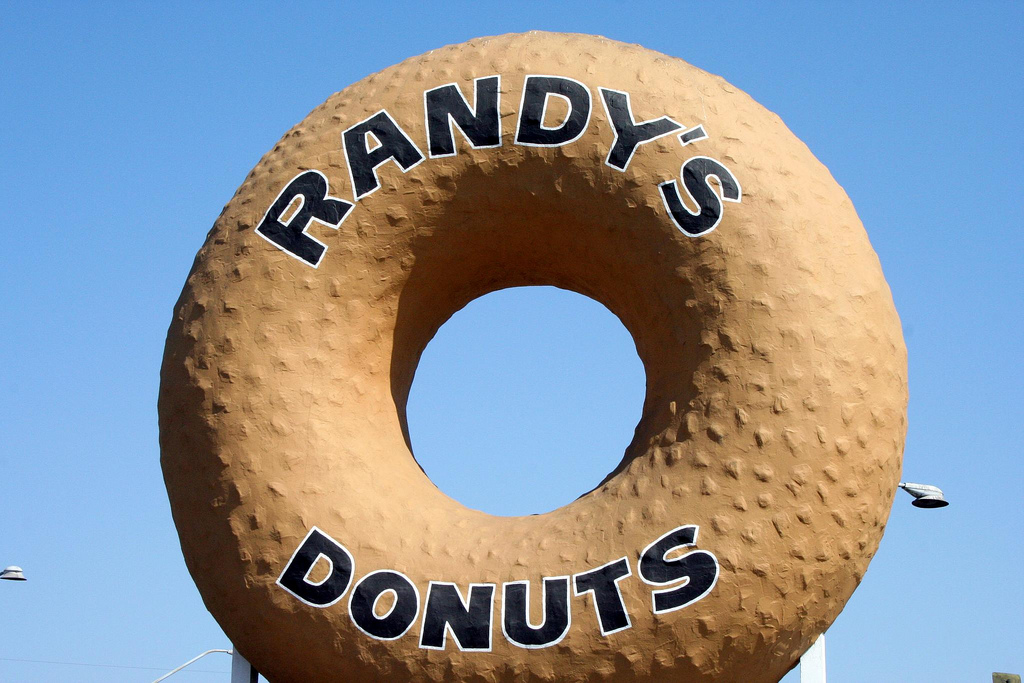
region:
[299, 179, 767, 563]
Blue sky can be seen through the center of the sign.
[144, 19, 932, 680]
a large brown doughnut-shaped sign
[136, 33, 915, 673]
large donunt shaped Randy Donunts sign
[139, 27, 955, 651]
Giant doughnut shop sign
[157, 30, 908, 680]
really large donut shaped sign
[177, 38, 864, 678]
The sign says Randy's Donuts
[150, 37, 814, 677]
There is a donut shaped sign for randy's donuts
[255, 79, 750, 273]
black and white lettering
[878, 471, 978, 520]
white protruding light to light up the donut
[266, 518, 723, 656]
black and white lettering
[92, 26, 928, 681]
giant brown sign with black and white letters advertising donuts for sale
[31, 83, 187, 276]
clear blue sky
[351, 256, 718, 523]
giant doughnut hole in "donut" sign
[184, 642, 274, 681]
pole holding up large donut sign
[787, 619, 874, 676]
support that is part of the structure holding up a sign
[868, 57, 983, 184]
cloudless sky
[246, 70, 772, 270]
large letter showing that something belongs to Randy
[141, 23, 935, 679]
a giant donut that says Randy's Donuts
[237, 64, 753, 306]
big words that say Randy's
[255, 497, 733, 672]
big words that say Donuts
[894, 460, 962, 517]
the light part of a light pole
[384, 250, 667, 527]
the donut hole of a giant donut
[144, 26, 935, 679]
a giant, bumpy textured donut statue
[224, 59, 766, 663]
giant words that say Randy's Donuts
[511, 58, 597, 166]
a giant letter D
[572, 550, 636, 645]
a giant letter T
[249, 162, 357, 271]
a giant letter R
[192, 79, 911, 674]
Round architectural object, meant to look like doughnut.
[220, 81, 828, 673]
Features black lettering, reading, "Randy's Donuts."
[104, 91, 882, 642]
Doughnut-shaped architecture shows pebbly texture and brown coloration.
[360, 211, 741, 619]
Doughnut hole is shadowed and shows sky behind it.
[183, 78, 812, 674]
Black letters are outlined in white.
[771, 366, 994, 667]
Doughnut-shaped item is high enough that street lamp appears to jut from side.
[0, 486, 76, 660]
Top of second light, of to side, on left.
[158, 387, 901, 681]
Doughnut architecture appears to be supported by white posts, positioned behind.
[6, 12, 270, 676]
Sky seems brightest at top and lighter as nears bottom of photo.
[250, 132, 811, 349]
Non-cursive lettering, in black and white.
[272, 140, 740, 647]
Reads, "Randy's Donuts."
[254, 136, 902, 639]
Doughnut sign shows pale tan exterior.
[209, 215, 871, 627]
Shows texture like sesame-seeds, throughout.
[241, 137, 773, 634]
Randy's misspelled sign looks more like a bagel than a doughnut.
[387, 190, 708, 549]
Crescent-shaped shadow around hole.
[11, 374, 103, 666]
Distant street lamp.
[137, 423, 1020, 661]
White bracing structures, supporting sign and nearby street light.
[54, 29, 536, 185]
Evenly-blue sky, with no clouds up at top.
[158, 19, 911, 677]
a large sign for a doughnut shop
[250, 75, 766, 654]
the name of the doughnut shop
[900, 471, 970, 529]
streetlight obscured by doughnut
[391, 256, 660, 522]
hole of a doughnut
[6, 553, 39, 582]
part of streetlight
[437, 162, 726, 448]
shaded region of a doughnut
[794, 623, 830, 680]
pole of a streetlight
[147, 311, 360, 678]
shaded region of a doughnut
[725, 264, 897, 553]
the surface of the doughnut has texture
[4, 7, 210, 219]
blue sky has no clouds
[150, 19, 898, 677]
large sign in doughnut shape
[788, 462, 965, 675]
streetlight behind a sign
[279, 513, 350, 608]
white borders on printed letters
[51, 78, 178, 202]
a clear blue sky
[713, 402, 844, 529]
a bumpy texture on an artificial doughnut